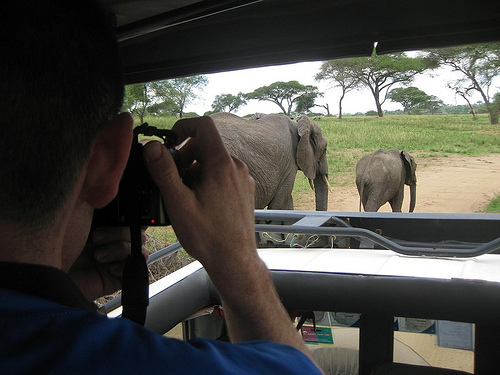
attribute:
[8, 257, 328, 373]
shirt — blue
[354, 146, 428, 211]
elephant — one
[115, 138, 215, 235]
camera — one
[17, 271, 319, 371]
shirt — blue, men's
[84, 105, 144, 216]
ear — male, human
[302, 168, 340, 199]
horns — elephant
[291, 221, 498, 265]
bar — metal, black